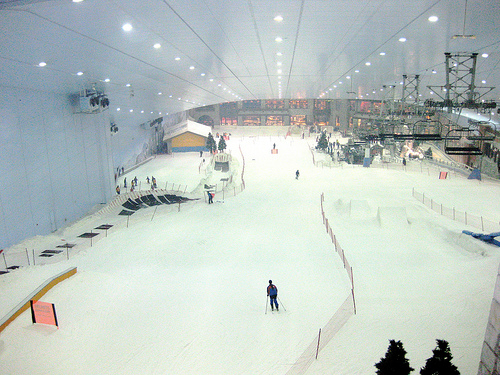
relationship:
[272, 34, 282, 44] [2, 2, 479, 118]
light in dome stadium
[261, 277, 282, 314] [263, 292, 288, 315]
skiier has 2 poles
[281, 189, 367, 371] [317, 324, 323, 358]
fence with pole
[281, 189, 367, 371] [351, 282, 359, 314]
fence with pole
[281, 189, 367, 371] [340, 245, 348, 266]
fence with pole